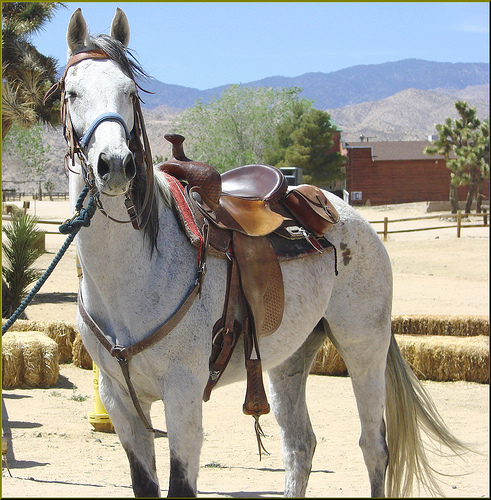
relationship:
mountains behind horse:
[3, 52, 490, 160] [50, 4, 411, 494]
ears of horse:
[65, 4, 131, 52] [50, 4, 411, 494]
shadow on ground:
[6, 378, 328, 492] [1, 199, 488, 499]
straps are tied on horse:
[82, 214, 261, 451] [50, 4, 411, 494]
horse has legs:
[50, 4, 411, 494] [93, 329, 395, 494]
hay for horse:
[3, 291, 485, 395] [50, 4, 411, 494]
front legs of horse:
[94, 377, 206, 495] [50, 4, 411, 494]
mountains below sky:
[3, 52, 490, 160] [4, 0, 489, 99]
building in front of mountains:
[336, 128, 484, 208] [3, 52, 490, 160]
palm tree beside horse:
[2, 4, 66, 149] [50, 4, 411, 494]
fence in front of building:
[8, 183, 487, 245] [336, 128, 484, 208]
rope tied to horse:
[3, 112, 136, 348] [50, 4, 411, 494]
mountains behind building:
[3, 52, 490, 160] [336, 128, 484, 208]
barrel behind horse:
[83, 353, 143, 438] [50, 4, 411, 494]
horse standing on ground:
[50, 4, 411, 494] [1, 199, 488, 499]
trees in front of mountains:
[2, 3, 490, 218] [3, 52, 490, 160]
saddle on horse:
[165, 133, 320, 416] [50, 4, 411, 494]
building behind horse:
[336, 128, 484, 208] [50, 4, 411, 494]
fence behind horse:
[8, 183, 487, 245] [50, 4, 411, 494]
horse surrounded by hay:
[50, 4, 411, 494] [3, 291, 485, 395]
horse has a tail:
[50, 4, 411, 494] [382, 332, 470, 493]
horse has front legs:
[50, 4, 411, 494] [94, 377, 206, 495]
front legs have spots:
[94, 377, 206, 495] [124, 451, 196, 499]